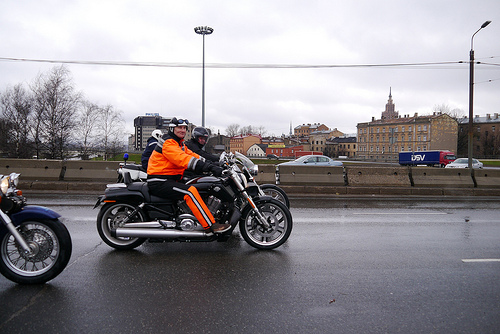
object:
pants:
[147, 180, 216, 230]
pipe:
[116, 228, 213, 237]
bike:
[92, 163, 292, 250]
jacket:
[147, 134, 206, 183]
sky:
[0, 0, 497, 99]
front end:
[0, 171, 73, 285]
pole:
[192, 26, 212, 127]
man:
[146, 117, 231, 236]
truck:
[399, 150, 456, 168]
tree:
[0, 66, 118, 154]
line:
[461, 258, 500, 263]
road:
[0, 246, 499, 333]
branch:
[56, 75, 72, 83]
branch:
[37, 75, 51, 83]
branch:
[46, 65, 70, 73]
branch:
[56, 72, 69, 78]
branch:
[52, 95, 71, 104]